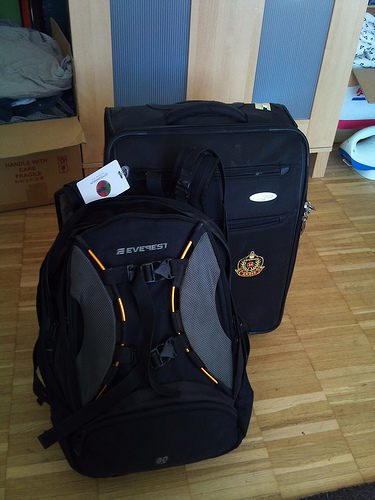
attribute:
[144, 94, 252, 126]
handle — black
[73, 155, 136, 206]
tag — in the picture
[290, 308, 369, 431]
floor — wooden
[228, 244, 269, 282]
emblem — gold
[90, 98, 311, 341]
bag — dark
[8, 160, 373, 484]
floor — in the picture, hardwood, wooden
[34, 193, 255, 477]
backpack — black, sitting 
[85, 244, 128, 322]
accent — yellow, grey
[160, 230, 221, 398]
accent — yellow, grey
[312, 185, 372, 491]
floor — wooden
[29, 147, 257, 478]
backpack — sitting, black 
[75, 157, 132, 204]
tag — luggage tag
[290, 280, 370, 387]
floor — wooden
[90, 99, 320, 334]
suitcase — black, rolling suitcase, in the picture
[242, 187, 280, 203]
decal — oval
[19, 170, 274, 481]
black backpack — zippered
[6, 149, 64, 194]
writing — red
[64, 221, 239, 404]
panels — gray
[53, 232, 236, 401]
backpack trim — orange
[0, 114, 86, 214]
box — cardboard